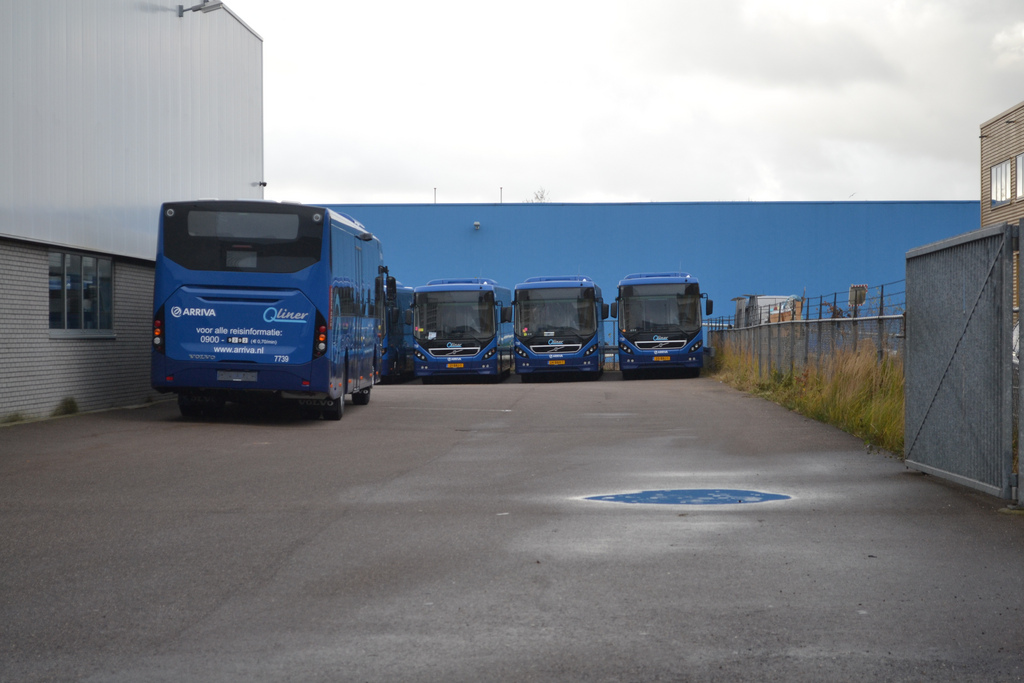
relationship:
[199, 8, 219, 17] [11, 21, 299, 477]
light on building